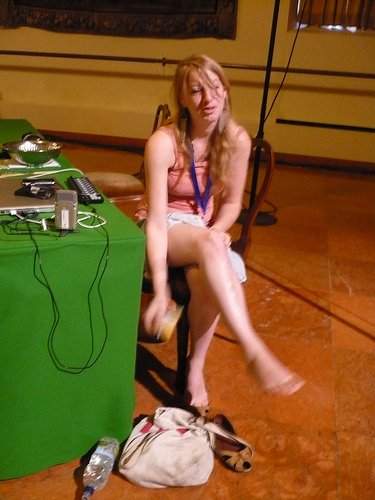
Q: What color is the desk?
A: Green.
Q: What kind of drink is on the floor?
A: Bottled water.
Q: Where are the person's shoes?
A: On the ground.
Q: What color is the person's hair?
A: Blonde.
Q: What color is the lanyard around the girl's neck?
A: Blue.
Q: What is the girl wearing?
A: A tank top and shorts.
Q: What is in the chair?
A: A woman.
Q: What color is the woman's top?
A: Pink.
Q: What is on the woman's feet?
A: Nothing.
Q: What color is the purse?
A: White.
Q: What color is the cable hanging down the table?
A: Black.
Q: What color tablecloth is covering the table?
A: Green.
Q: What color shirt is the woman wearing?
A: Pink.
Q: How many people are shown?
A: One.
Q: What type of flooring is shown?
A: Tile.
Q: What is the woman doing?
A: Sitting.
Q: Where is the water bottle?
A: On the floor.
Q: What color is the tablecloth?
A: Green.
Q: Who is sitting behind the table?
A: The woman.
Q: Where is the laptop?
A: On the table.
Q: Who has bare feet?
A: The woman.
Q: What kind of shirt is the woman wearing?
A: A tank top.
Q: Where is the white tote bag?
A: On the ground.